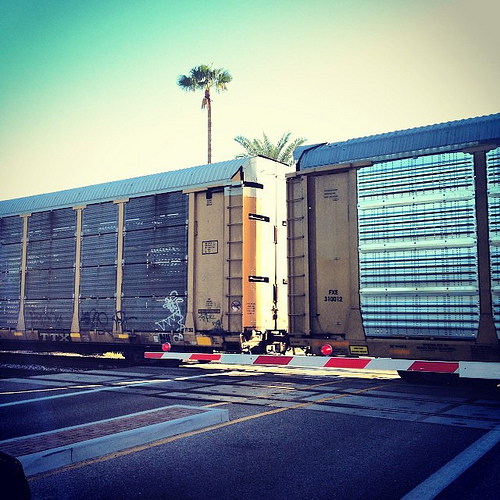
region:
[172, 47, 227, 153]
a tall palm tree behind the train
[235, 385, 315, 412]
yellow lines on the street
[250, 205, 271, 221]
a small rectangle window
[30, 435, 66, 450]
red bricks in the median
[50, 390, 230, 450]
a brick and cement median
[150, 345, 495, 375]
a red and white caution arm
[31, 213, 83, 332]
corrugated panel on the train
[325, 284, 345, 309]
black lettering on the train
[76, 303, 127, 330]
black graffiti on the train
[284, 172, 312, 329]
yellow metal rungs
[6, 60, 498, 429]
a train crossing a street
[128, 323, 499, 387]
a crossing bar on a street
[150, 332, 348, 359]
two red lights on a crossing bar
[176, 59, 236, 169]
a tall tree behind a train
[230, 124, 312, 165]
leaves sticking above a train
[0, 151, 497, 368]
two train cars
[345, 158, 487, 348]
meetal siding on a train car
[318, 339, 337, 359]
a red light near a train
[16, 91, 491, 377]
two yellow train cars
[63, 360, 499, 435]
train tracks on the road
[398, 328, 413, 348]
part of a train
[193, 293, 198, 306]
edge of a train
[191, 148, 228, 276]
part of a cabin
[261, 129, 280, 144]
part of a leaf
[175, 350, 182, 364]
bottom of a train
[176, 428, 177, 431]
part of a lawn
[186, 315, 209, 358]
part of a rail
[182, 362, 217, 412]
edge of a rail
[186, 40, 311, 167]
A tall palm tree behind train.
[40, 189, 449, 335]
Train on the track.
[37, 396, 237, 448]
Median on the road.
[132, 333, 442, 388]
red and white railroad railing.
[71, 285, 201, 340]
Grafitti on the train car.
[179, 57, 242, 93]
The tree has leaves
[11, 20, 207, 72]
The sky has dark cloud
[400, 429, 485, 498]
White lines in the street.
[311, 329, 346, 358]
Red lights on train.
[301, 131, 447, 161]
Aluminum covering on train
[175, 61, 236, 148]
a tree behind the train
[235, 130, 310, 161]
plant behind the tree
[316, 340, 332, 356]
indicator in the sidewalk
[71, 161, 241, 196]
roof of the train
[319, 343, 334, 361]
train indicator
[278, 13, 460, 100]
sky with clouds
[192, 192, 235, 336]
door of the train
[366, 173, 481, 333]
steel shutter of the train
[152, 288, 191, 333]
something scribbled in the train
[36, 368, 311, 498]
road marked with white and yellow color